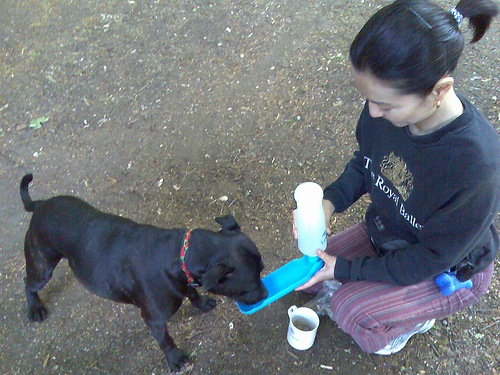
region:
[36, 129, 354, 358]
a dog on the ground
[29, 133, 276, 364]
a black dog on the ground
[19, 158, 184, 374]
a small dog on the ground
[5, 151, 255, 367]
a small black dog on teh ground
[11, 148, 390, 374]
a black dog wearing a collar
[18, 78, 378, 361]
a small dog wearing a collar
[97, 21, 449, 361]
a woman giving dog water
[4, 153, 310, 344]
a dog drinkign water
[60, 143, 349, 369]
a black dog drinking water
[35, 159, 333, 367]
a small dog drinking water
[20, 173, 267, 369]
dog with short black hair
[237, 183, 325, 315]
portable dog water bowl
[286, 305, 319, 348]
white coffee cup on the ground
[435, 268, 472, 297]
poop bag holder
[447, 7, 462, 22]
rubber band in the woman's hair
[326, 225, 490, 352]
purple striped pants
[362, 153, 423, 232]
design on the sweatshirt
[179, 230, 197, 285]
red collar on the dog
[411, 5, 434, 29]
black hair clip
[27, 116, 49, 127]
green leaf on the ground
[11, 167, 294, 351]
black dog wearing red collar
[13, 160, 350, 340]
dog drinking water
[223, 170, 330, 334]
water bottle for dogs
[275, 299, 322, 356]
white cup with water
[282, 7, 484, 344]
woman wearing blue sweatshirt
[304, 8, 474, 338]
woman with hair in ponytail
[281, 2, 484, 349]
woman wearing striped pants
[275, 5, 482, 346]
woman holding water bottle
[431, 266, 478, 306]
dog bone clipped to woman's waist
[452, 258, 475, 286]
dog brush in woman's pocket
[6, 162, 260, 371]
black dog drinking from bowl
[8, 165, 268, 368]
dog drinking from bowl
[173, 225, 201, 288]
collar on dog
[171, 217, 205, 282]
collar on black dog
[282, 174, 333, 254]
woman holds bottle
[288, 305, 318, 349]
cup on the ground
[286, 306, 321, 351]
white cup on the ground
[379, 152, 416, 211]
logo on the shirt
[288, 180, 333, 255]
blue bottle in woman's hand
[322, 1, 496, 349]
woman kneeling down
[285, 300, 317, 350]
a stained white coffee mug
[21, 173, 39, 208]
black tail on the dog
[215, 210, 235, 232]
an ear on the black dog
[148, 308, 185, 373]
a front leg on black dog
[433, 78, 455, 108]
a gold earring on woman's ear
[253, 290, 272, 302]
dog eating from blue dish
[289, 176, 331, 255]
woman's hand holding plastic bottle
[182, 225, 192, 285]
a red collar around dog's neck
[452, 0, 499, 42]
band around the woman's pony tail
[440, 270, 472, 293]
a plastic object in woman's pocket